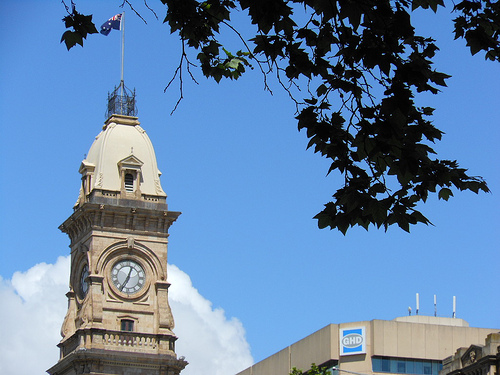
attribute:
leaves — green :
[53, 2, 497, 222]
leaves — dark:
[165, 7, 498, 233]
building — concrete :
[237, 317, 482, 373]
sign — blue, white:
[330, 318, 397, 358]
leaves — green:
[333, 108, 473, 215]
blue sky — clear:
[1, 0, 498, 373]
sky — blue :
[221, 94, 424, 243]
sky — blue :
[194, 124, 304, 266]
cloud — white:
[1, 250, 258, 374]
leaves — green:
[278, 68, 491, 228]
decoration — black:
[103, 79, 140, 121]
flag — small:
[98, 12, 122, 34]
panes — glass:
[311, 356, 438, 372]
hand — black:
[127, 264, 134, 277]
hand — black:
[117, 277, 129, 292]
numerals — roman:
[111, 259, 142, 293]